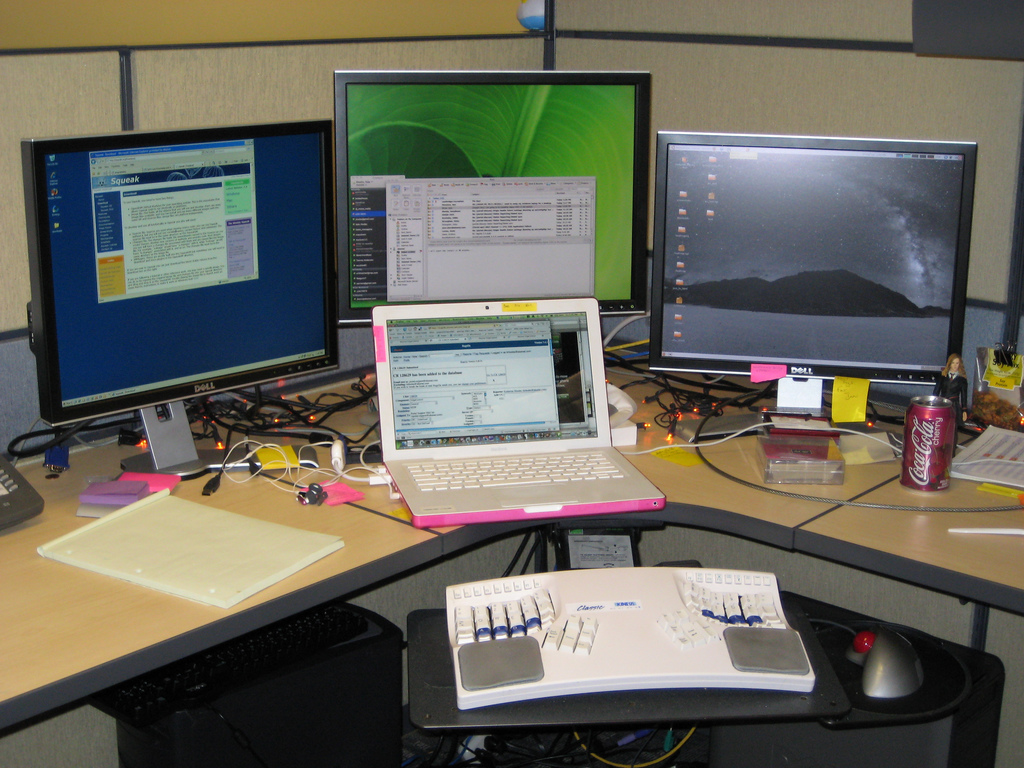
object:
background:
[350, 80, 637, 306]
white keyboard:
[443, 566, 816, 711]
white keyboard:
[384, 445, 661, 516]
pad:
[298, 479, 367, 507]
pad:
[118, 471, 183, 493]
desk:
[0, 354, 1024, 732]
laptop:
[369, 297, 668, 529]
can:
[901, 395, 956, 497]